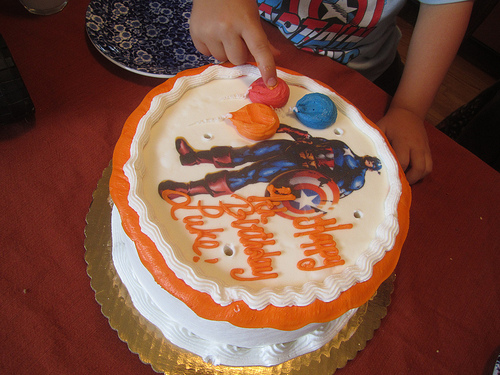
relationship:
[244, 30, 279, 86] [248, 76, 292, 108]
finger touching ball of frosting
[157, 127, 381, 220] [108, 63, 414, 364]
action hero on cake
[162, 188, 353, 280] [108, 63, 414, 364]
writing on cake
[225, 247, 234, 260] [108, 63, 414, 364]
hole in cake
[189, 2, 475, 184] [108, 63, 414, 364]
child has finger in cake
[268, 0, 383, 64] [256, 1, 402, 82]
captain america on child shirt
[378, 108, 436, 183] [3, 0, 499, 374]
hand on table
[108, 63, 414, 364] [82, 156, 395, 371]
cake on a platter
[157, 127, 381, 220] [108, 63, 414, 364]
captain america on cake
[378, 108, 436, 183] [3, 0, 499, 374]
hand resting on table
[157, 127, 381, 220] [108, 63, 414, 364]
captain america on top of cake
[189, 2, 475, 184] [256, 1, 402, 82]
child hascaptain america shirt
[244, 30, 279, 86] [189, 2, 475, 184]
finger of child